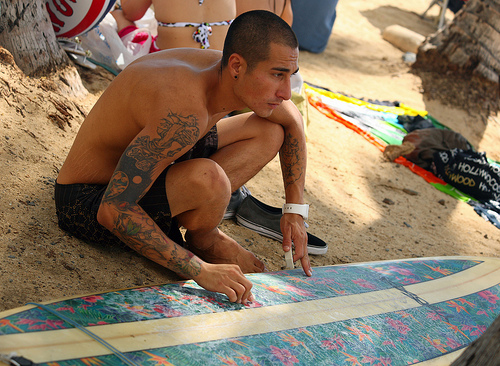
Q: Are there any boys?
A: No, there are no boys.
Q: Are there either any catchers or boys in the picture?
A: No, there are no boys or catchers.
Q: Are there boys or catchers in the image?
A: No, there are no boys or catchers.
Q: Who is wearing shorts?
A: The man is wearing shorts.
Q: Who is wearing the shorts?
A: The man is wearing shorts.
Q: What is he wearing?
A: The man is wearing shorts.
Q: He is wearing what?
A: The man is wearing shorts.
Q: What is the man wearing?
A: The man is wearing shorts.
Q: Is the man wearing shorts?
A: Yes, the man is wearing shorts.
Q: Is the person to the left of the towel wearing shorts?
A: Yes, the man is wearing shorts.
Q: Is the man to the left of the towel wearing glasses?
A: No, the man is wearing shorts.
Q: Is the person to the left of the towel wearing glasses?
A: No, the man is wearing shorts.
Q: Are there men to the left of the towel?
A: Yes, there is a man to the left of the towel.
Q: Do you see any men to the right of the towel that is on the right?
A: No, the man is to the left of the towel.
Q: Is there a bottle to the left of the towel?
A: No, there is a man to the left of the towel.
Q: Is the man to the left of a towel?
A: Yes, the man is to the left of a towel.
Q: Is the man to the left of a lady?
A: No, the man is to the left of a towel.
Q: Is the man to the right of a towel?
A: No, the man is to the left of a towel.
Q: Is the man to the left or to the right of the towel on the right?
A: The man is to the left of the towel.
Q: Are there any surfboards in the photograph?
A: Yes, there is a surfboard.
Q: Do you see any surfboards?
A: Yes, there is a surfboard.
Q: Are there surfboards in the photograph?
A: Yes, there is a surfboard.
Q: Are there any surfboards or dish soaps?
A: Yes, there is a surfboard.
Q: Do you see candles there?
A: No, there are no candles.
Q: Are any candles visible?
A: No, there are no candles.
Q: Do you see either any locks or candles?
A: No, there are no candles or locks.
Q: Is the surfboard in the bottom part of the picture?
A: Yes, the surfboard is in the bottom of the image.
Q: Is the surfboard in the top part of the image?
A: No, the surfboard is in the bottom of the image.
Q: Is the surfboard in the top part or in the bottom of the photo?
A: The surfboard is in the bottom of the image.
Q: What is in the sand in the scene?
A: The surfboard is in the sand.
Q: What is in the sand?
A: The surfboard is in the sand.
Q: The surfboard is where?
A: The surfboard is in the sand.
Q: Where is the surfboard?
A: The surfboard is in the sand.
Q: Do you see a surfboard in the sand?
A: Yes, there is a surfboard in the sand.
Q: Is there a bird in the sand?
A: No, there is a surfboard in the sand.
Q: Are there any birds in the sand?
A: No, there is a surfboard in the sand.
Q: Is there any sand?
A: Yes, there is sand.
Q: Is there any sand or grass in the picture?
A: Yes, there is sand.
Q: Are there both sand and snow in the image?
A: No, there is sand but no snow.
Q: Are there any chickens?
A: No, there are no chickens.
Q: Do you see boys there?
A: No, there are no boys.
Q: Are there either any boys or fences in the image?
A: No, there are no boys or fences.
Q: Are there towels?
A: Yes, there is a towel.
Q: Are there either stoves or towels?
A: Yes, there is a towel.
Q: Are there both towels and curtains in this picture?
A: No, there is a towel but no curtains.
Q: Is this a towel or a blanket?
A: This is a towel.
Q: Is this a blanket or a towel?
A: This is a towel.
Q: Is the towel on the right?
A: Yes, the towel is on the right of the image.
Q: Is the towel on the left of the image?
A: No, the towel is on the right of the image.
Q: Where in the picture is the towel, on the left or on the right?
A: The towel is on the right of the image.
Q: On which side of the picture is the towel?
A: The towel is on the right of the image.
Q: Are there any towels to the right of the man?
A: Yes, there is a towel to the right of the man.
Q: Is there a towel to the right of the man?
A: Yes, there is a towel to the right of the man.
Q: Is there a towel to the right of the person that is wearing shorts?
A: Yes, there is a towel to the right of the man.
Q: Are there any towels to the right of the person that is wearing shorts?
A: Yes, there is a towel to the right of the man.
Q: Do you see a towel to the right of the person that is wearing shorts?
A: Yes, there is a towel to the right of the man.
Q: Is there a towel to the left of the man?
A: No, the towel is to the right of the man.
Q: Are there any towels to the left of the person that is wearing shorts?
A: No, the towel is to the right of the man.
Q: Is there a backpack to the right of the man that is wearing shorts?
A: No, there is a towel to the right of the man.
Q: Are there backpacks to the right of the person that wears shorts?
A: No, there is a towel to the right of the man.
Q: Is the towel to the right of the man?
A: Yes, the towel is to the right of the man.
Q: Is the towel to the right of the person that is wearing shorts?
A: Yes, the towel is to the right of the man.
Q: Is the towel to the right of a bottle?
A: No, the towel is to the right of the man.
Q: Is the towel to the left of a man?
A: No, the towel is to the right of a man.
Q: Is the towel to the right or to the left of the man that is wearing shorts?
A: The towel is to the right of the man.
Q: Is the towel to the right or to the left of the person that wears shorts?
A: The towel is to the right of the man.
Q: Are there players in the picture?
A: No, there are no players.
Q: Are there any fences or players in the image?
A: No, there are no players or fences.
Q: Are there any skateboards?
A: No, there are no skateboards.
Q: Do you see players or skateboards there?
A: No, there are no skateboards or players.